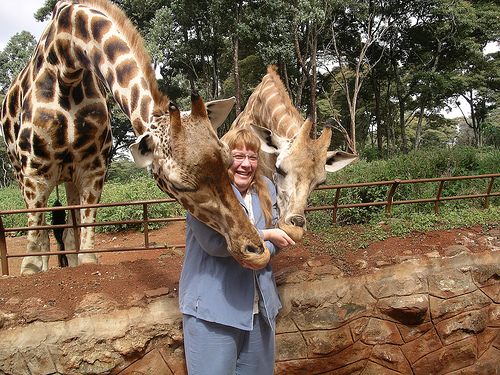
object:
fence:
[0, 172, 497, 269]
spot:
[44, 43, 60, 67]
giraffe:
[0, 0, 241, 271]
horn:
[168, 105, 181, 134]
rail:
[44, 181, 148, 275]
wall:
[47, 300, 140, 360]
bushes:
[0, 144, 475, 236]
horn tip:
[166, 100, 177, 112]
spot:
[114, 57, 141, 88]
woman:
[172, 119, 299, 374]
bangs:
[219, 128, 263, 155]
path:
[0, 222, 190, 276]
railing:
[2, 167, 499, 275]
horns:
[295, 114, 314, 143]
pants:
[180, 307, 276, 373]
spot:
[17, 69, 39, 99]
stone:
[369, 273, 429, 340]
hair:
[212, 127, 274, 227]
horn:
[192, 89, 207, 118]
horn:
[317, 125, 331, 149]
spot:
[33, 42, 46, 81]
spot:
[15, 120, 32, 150]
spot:
[102, 37, 129, 64]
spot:
[89, 14, 113, 44]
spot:
[36, 67, 56, 102]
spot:
[93, 177, 103, 189]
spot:
[276, 117, 294, 132]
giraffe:
[227, 61, 360, 244]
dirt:
[1, 234, 323, 334]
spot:
[55, 36, 76, 72]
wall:
[35, 179, 195, 254]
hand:
[265, 227, 297, 249]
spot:
[123, 81, 140, 115]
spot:
[140, 77, 158, 86]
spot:
[24, 176, 34, 189]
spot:
[72, 119, 99, 150]